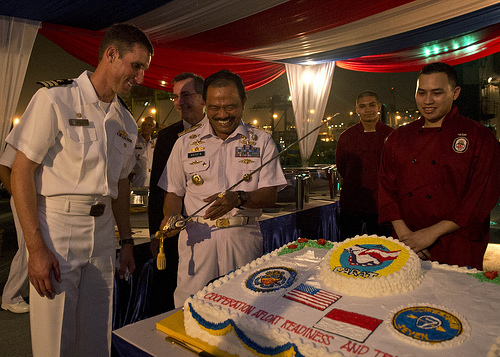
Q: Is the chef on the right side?
A: Yes, the chef is on the right of the image.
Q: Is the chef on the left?
A: No, the chef is on the right of the image.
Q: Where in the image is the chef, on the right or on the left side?
A: The chef is on the right of the image.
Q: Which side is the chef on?
A: The chef is on the right of the image.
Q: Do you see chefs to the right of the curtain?
A: Yes, there is a chef to the right of the curtain.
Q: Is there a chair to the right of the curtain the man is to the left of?
A: No, there is a chef to the right of the curtain.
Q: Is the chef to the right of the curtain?
A: Yes, the chef is to the right of the curtain.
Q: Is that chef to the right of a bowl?
A: No, the chef is to the right of the curtain.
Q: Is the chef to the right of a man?
A: Yes, the chef is to the right of a man.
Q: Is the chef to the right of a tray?
A: No, the chef is to the right of a man.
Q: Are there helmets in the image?
A: No, there are no helmets.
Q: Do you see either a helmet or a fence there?
A: No, there are no helmets or fences.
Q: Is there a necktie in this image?
A: No, there are no ties.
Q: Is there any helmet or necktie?
A: No, there are no ties or helmets.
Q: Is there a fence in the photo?
A: No, there are no fences.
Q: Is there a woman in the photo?
A: No, there are no women.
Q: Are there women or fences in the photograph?
A: No, there are no women or fences.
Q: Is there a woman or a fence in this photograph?
A: No, there are no women or fences.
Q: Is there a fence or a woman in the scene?
A: No, there are no women or fences.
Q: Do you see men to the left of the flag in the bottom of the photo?
A: Yes, there is a man to the left of the flag.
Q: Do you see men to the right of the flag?
A: No, the man is to the left of the flag.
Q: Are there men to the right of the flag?
A: No, the man is to the left of the flag.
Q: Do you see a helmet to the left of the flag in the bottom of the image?
A: No, there is a man to the left of the flag.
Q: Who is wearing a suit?
A: The man is wearing a suit.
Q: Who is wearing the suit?
A: The man is wearing a suit.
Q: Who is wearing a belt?
A: The man is wearing a belt.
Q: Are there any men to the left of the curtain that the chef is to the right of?
A: Yes, there is a man to the left of the curtain.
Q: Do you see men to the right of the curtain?
A: No, the man is to the left of the curtain.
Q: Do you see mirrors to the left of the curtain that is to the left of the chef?
A: No, there is a man to the left of the curtain.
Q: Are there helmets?
A: No, there are no helmets.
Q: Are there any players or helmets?
A: No, there are no helmets or players.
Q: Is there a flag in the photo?
A: Yes, there is a flag.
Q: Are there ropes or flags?
A: Yes, there is a flag.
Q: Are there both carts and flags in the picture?
A: No, there is a flag but no carts.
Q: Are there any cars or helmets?
A: No, there are no helmets or cars.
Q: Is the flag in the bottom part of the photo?
A: Yes, the flag is in the bottom of the image.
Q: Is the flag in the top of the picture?
A: No, the flag is in the bottom of the image.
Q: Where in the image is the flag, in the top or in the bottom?
A: The flag is in the bottom of the image.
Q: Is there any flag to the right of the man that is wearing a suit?
A: Yes, there is a flag to the right of the man.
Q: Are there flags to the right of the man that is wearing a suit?
A: Yes, there is a flag to the right of the man.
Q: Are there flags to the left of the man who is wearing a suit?
A: No, the flag is to the right of the man.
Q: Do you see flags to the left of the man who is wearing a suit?
A: No, the flag is to the right of the man.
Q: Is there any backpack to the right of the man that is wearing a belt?
A: No, there is a flag to the right of the man.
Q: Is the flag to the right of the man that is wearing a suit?
A: Yes, the flag is to the right of the man.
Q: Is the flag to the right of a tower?
A: No, the flag is to the right of the man.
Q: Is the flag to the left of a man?
A: No, the flag is to the right of a man.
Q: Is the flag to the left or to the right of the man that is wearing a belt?
A: The flag is to the right of the man.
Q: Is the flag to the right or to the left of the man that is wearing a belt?
A: The flag is to the right of the man.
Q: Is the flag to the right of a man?
A: Yes, the flag is to the right of a man.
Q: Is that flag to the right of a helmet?
A: No, the flag is to the right of a man.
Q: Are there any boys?
A: No, there are no boys.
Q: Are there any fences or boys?
A: No, there are no boys or fences.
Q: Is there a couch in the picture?
A: No, there are no couches.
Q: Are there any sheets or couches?
A: No, there are no couches or sheets.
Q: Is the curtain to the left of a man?
A: No, the curtain is to the right of a man.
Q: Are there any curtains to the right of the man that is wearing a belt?
A: Yes, there is a curtain to the right of the man.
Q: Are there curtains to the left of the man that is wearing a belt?
A: No, the curtain is to the right of the man.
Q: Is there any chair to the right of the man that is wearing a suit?
A: No, there is a curtain to the right of the man.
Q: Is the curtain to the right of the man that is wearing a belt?
A: Yes, the curtain is to the right of the man.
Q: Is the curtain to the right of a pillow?
A: No, the curtain is to the right of the man.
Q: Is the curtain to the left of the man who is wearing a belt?
A: No, the curtain is to the right of the man.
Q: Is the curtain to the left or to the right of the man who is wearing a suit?
A: The curtain is to the right of the man.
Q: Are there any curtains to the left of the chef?
A: Yes, there is a curtain to the left of the chef.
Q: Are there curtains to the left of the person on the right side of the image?
A: Yes, there is a curtain to the left of the chef.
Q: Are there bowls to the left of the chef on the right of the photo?
A: No, there is a curtain to the left of the chef.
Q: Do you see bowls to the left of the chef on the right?
A: No, there is a curtain to the left of the chef.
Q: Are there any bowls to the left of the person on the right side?
A: No, there is a curtain to the left of the chef.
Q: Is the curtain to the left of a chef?
A: Yes, the curtain is to the left of a chef.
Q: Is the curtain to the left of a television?
A: No, the curtain is to the left of a chef.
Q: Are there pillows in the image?
A: No, there are no pillows.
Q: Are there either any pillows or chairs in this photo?
A: No, there are no pillows or chairs.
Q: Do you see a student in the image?
A: No, there are no students.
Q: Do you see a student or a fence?
A: No, there are no students or fences.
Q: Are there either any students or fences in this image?
A: No, there are no students or fences.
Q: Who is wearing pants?
A: The man is wearing pants.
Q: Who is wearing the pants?
A: The man is wearing pants.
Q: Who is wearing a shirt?
A: The man is wearing a shirt.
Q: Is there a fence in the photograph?
A: No, there are no fences.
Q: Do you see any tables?
A: Yes, there is a table.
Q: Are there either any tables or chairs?
A: Yes, there is a table.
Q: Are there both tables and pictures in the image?
A: No, there is a table but no pictures.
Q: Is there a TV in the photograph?
A: No, there are no televisions.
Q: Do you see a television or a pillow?
A: No, there are no televisions or pillows.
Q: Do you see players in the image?
A: No, there are no players.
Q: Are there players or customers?
A: No, there are no players or customers.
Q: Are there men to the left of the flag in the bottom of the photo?
A: Yes, there is a man to the left of the flag.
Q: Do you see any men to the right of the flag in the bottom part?
A: No, the man is to the left of the flag.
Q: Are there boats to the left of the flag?
A: No, there is a man to the left of the flag.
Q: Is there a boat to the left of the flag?
A: No, there is a man to the left of the flag.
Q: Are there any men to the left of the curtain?
A: Yes, there is a man to the left of the curtain.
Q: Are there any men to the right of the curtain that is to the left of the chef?
A: No, the man is to the left of the curtain.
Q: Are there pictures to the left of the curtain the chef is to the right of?
A: No, there is a man to the left of the curtain.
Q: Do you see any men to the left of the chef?
A: Yes, there is a man to the left of the chef.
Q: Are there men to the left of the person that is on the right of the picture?
A: Yes, there is a man to the left of the chef.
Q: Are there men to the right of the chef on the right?
A: No, the man is to the left of the chef.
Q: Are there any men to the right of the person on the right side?
A: No, the man is to the left of the chef.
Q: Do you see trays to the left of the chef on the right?
A: No, there is a man to the left of the chef.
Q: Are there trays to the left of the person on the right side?
A: No, there is a man to the left of the chef.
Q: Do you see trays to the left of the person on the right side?
A: No, there is a man to the left of the chef.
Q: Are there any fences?
A: No, there are no fences.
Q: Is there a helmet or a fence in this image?
A: No, there are no fences or helmets.